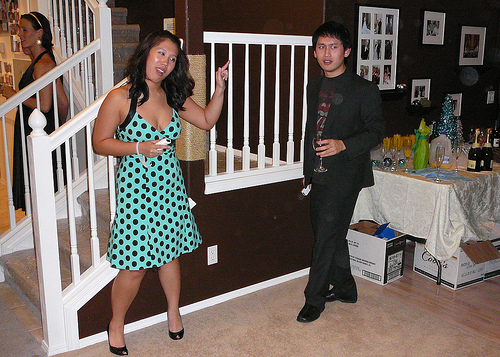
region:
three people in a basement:
[2, 9, 381, 353]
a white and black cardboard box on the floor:
[347, 214, 406, 283]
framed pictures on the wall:
[358, 5, 399, 90]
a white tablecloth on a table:
[348, 154, 499, 261]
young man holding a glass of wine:
[309, 135, 339, 172]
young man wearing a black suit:
[297, 21, 384, 323]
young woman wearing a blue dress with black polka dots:
[106, 79, 202, 266]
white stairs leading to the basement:
[0, 0, 310, 355]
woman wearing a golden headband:
[25, 12, 42, 33]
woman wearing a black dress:
[9, 49, 63, 212]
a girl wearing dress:
[94, 29, 233, 350]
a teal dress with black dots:
[109, 97, 201, 267]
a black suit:
[304, 70, 381, 312]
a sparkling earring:
[34, 38, 42, 45]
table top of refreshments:
[376, 125, 499, 223]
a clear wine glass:
[310, 132, 330, 178]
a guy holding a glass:
[298, 23, 365, 320]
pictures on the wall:
[353, 4, 489, 121]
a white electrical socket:
[204, 243, 221, 265]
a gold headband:
[26, 10, 41, 24]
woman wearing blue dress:
[65, 18, 256, 278]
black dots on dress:
[119, 166, 175, 236]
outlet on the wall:
[191, 231, 234, 281]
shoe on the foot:
[288, 294, 333, 330]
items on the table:
[381, 110, 493, 185]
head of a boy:
[301, 13, 365, 87]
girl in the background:
[8, 9, 63, 84]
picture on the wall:
[408, 12, 464, 47]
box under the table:
[406, 234, 493, 304]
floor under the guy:
[336, 310, 408, 352]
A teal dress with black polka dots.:
[104, 80, 202, 271]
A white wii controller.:
[152, 133, 173, 158]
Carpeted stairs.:
[1, 0, 205, 313]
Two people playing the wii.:
[88, 23, 386, 354]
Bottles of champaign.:
[467, 127, 495, 174]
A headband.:
[27, 10, 44, 26]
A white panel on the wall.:
[205, 242, 218, 269]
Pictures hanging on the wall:
[355, 4, 487, 121]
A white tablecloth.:
[346, 150, 498, 260]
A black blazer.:
[301, 70, 387, 193]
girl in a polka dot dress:
[80, 18, 275, 355]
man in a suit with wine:
[277, 31, 396, 326]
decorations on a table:
[388, 102, 498, 184]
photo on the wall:
[350, 4, 405, 86]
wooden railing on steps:
[22, 92, 94, 331]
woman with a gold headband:
[7, 8, 73, 226]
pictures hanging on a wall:
[348, 3, 495, 100]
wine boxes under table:
[351, 217, 498, 292]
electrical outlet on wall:
[202, 234, 231, 279]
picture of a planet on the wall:
[452, 65, 473, 87]